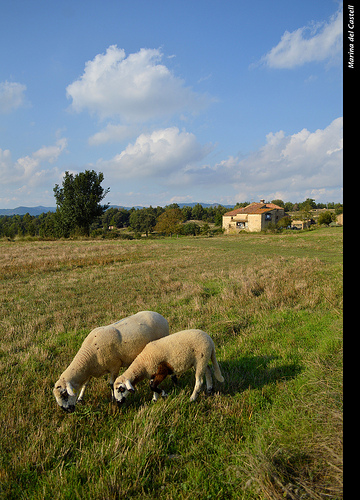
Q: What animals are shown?
A: Sheep.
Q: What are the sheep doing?
A: Eating grass.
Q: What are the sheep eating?
A: Grass.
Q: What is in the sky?
A: Clouds.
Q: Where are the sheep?
A: In a field.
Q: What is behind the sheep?
A: A house.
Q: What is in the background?
A: Trees.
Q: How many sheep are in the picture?
A: 2.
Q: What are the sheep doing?
A: Eating grass.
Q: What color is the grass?
A: Green and brown.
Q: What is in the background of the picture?
A: A house.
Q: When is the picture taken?
A: During the daytime.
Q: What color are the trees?
A: Green.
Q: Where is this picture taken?
A: In a pasture.